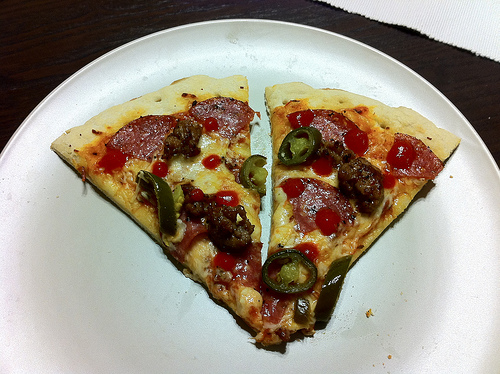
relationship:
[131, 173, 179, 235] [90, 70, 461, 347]
jalapeno on pizza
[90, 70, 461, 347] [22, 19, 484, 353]
pizza on pan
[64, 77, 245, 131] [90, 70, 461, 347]
crust on pizza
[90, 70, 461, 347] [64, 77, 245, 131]
pizza has crust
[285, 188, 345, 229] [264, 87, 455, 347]
pepperoni sitting on pizza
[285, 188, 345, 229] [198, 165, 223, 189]
pepperoni covered with cheese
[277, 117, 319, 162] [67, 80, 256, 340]
pepper sitting on pizza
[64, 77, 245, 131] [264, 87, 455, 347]
crust part of pizza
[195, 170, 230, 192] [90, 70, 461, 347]
cheese part of pizza